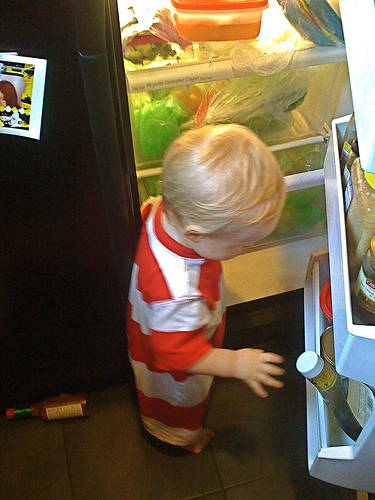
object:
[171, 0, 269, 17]
lid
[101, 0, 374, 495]
fridge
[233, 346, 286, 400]
hand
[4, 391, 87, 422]
bottle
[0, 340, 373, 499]
floor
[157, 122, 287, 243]
hair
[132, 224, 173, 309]
stripe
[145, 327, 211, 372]
stripe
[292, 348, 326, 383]
cap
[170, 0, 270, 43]
container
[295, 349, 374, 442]
bottle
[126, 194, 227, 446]
shirt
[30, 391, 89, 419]
tabasco sauce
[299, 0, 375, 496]
door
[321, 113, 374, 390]
fridge shelf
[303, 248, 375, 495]
refrigerator shelf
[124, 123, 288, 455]
boy